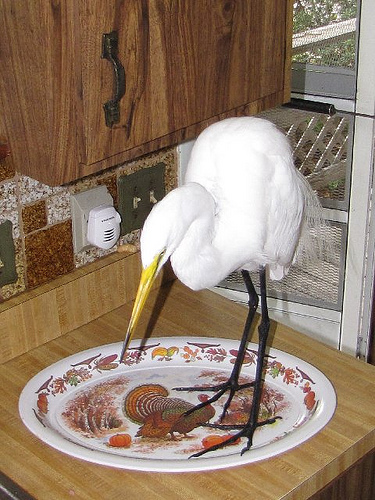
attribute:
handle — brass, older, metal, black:
[102, 33, 126, 127]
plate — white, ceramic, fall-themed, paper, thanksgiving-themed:
[18, 336, 336, 471]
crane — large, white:
[121, 118, 318, 459]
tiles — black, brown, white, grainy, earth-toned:
[1, 155, 177, 293]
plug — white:
[70, 194, 122, 249]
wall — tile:
[1, 130, 184, 361]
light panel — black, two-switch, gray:
[115, 165, 166, 233]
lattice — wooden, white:
[277, 116, 357, 182]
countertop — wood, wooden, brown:
[2, 284, 373, 498]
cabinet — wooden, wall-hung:
[0, 1, 292, 185]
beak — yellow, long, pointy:
[116, 263, 162, 365]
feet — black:
[171, 379, 280, 459]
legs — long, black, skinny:
[230, 270, 272, 415]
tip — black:
[120, 330, 137, 364]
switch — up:
[132, 196, 141, 209]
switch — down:
[147, 191, 157, 204]